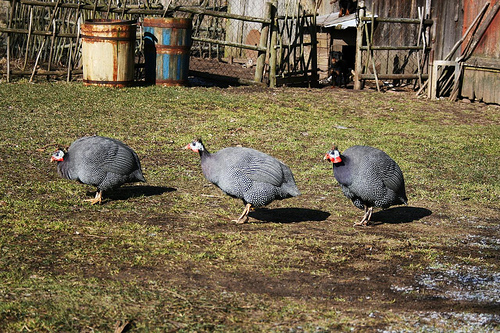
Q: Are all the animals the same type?
A: No, there are both turkey and birds.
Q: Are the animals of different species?
A: Yes, they are turkey and birds.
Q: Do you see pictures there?
A: No, there are no pictures.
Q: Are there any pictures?
A: No, there are no pictures.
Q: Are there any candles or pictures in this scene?
A: No, there are no pictures or candles.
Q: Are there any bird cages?
A: No, there are no bird cages.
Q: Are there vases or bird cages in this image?
A: No, there are no bird cages or vases.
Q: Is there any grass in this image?
A: Yes, there is grass.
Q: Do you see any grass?
A: Yes, there is grass.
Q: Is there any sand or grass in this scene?
A: Yes, there is grass.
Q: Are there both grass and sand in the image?
A: No, there is grass but no sand.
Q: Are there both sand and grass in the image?
A: No, there is grass but no sand.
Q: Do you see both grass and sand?
A: No, there is grass but no sand.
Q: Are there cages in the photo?
A: No, there are no cages.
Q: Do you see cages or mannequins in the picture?
A: No, there are no cages or mannequins.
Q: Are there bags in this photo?
A: No, there are no bags.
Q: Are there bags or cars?
A: No, there are no bags or cars.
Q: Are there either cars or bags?
A: No, there are no bags or cars.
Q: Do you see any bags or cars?
A: No, there are no bags or cars.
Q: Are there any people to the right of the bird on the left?
A: Yes, there is a person to the right of the bird.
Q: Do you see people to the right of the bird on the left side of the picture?
A: Yes, there is a person to the right of the bird.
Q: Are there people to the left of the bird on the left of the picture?
A: No, the person is to the right of the bird.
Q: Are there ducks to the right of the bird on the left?
A: No, there is a person to the right of the bird.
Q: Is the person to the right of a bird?
A: Yes, the person is to the right of a bird.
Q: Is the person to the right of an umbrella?
A: No, the person is to the right of a bird.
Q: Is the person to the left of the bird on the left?
A: No, the person is to the right of the bird.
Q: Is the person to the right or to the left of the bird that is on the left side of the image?
A: The person is to the right of the bird.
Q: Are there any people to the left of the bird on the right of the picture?
A: Yes, there is a person to the left of the bird.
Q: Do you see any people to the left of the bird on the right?
A: Yes, there is a person to the left of the bird.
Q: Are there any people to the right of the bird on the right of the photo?
A: No, the person is to the left of the bird.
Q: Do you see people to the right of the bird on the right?
A: No, the person is to the left of the bird.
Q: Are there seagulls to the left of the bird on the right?
A: No, there is a person to the left of the bird.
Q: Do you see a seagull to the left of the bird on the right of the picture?
A: No, there is a person to the left of the bird.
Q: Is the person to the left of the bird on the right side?
A: Yes, the person is to the left of the bird.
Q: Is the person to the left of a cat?
A: No, the person is to the left of the bird.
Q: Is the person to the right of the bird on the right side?
A: No, the person is to the left of the bird.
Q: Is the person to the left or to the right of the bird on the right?
A: The person is to the left of the bird.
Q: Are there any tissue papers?
A: No, there are no tissue papers.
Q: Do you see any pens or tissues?
A: No, there are no tissues or pens.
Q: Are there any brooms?
A: No, there are no brooms.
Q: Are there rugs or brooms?
A: No, there are no brooms or rugs.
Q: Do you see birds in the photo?
A: Yes, there is a bird.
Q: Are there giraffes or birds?
A: Yes, there is a bird.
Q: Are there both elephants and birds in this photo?
A: No, there is a bird but no elephants.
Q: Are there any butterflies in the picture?
A: No, there are no butterflies.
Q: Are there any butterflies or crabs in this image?
A: No, there are no butterflies or crabs.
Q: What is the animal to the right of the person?
A: The animal is a bird.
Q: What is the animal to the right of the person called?
A: The animal is a bird.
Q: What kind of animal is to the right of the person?
A: The animal is a bird.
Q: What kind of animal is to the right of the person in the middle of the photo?
A: The animal is a bird.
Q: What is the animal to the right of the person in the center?
A: The animal is a bird.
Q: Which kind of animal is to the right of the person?
A: The animal is a bird.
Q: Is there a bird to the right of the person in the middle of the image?
A: Yes, there is a bird to the right of the person.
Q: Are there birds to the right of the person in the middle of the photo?
A: Yes, there is a bird to the right of the person.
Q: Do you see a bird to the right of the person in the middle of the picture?
A: Yes, there is a bird to the right of the person.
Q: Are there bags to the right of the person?
A: No, there is a bird to the right of the person.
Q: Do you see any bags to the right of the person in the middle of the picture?
A: No, there is a bird to the right of the person.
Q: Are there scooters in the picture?
A: No, there are no scooters.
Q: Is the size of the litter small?
A: Yes, the litter is small.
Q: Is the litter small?
A: Yes, the litter is small.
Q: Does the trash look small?
A: Yes, the trash is small.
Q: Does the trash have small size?
A: Yes, the trash is small.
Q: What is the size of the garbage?
A: The garbage is small.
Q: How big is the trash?
A: The trash is small.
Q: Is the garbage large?
A: No, the garbage is small.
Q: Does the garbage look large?
A: No, the garbage is small.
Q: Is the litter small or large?
A: The litter is small.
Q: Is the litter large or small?
A: The litter is small.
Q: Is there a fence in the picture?
A: Yes, there is a fence.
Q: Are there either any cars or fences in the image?
A: Yes, there is a fence.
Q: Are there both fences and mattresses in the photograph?
A: No, there is a fence but no mattresses.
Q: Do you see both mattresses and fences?
A: No, there is a fence but no mattresses.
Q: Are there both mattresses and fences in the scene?
A: No, there is a fence but no mattresses.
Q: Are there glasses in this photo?
A: No, there are no glasses.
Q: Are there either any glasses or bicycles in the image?
A: No, there are no glasses or bicycles.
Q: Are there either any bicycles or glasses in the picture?
A: No, there are no glasses or bicycles.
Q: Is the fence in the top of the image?
A: Yes, the fence is in the top of the image.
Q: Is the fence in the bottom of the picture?
A: No, the fence is in the top of the image.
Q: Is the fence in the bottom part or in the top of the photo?
A: The fence is in the top of the image.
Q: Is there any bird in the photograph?
A: Yes, there is a bird.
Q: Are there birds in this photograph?
A: Yes, there is a bird.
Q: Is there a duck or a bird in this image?
A: Yes, there is a bird.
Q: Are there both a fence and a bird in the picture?
A: Yes, there are both a bird and a fence.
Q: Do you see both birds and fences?
A: Yes, there are both a bird and a fence.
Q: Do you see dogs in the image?
A: No, there are no dogs.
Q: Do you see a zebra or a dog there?
A: No, there are no dogs or zebras.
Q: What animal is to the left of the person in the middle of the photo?
A: The animal is a bird.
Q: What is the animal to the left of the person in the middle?
A: The animal is a bird.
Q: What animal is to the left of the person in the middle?
A: The animal is a bird.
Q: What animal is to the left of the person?
A: The animal is a bird.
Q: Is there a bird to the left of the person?
A: Yes, there is a bird to the left of the person.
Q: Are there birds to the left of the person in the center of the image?
A: Yes, there is a bird to the left of the person.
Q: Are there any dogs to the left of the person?
A: No, there is a bird to the left of the person.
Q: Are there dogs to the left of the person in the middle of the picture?
A: No, there is a bird to the left of the person.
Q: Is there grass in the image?
A: Yes, there is grass.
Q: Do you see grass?
A: Yes, there is grass.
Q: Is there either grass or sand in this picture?
A: Yes, there is grass.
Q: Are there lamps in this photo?
A: No, there are no lamps.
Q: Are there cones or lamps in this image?
A: No, there are no lamps or cones.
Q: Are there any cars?
A: No, there are no cars.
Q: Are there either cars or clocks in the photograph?
A: No, there are no cars or clocks.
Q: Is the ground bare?
A: Yes, the ground is bare.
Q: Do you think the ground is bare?
A: Yes, the ground is bare.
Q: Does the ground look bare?
A: Yes, the ground is bare.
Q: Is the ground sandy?
A: No, the ground is bare.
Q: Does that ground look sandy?
A: No, the ground is bare.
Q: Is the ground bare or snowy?
A: The ground is bare.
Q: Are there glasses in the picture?
A: No, there are no glasses.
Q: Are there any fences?
A: Yes, there is a fence.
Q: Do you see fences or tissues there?
A: Yes, there is a fence.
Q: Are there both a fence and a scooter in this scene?
A: No, there is a fence but no scooters.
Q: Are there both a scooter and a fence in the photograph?
A: No, there is a fence but no scooters.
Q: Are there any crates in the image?
A: No, there are no crates.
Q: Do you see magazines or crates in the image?
A: No, there are no crates or magazines.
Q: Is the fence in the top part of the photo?
A: Yes, the fence is in the top of the image.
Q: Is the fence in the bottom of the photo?
A: No, the fence is in the top of the image.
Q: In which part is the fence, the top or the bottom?
A: The fence is in the top of the image.